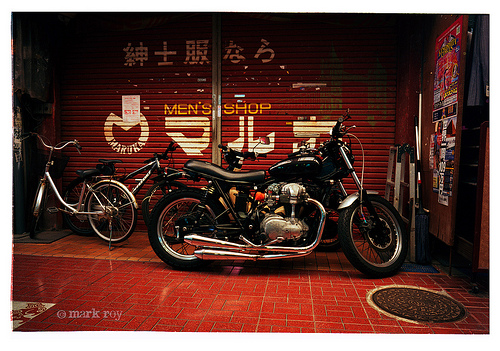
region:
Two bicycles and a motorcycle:
[26, 127, 431, 304]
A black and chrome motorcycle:
[138, 127, 425, 304]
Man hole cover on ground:
[363, 278, 467, 338]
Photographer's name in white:
[53, 303, 130, 325]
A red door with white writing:
[61, 69, 395, 240]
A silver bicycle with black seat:
[25, 134, 135, 250]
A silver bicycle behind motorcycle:
[21, 123, 140, 255]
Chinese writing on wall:
[115, 37, 300, 84]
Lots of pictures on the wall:
[424, 32, 469, 224]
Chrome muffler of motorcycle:
[177, 226, 310, 270]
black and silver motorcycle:
[182, 137, 374, 265]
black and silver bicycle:
[25, 145, 130, 247]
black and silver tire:
[337, 189, 404, 274]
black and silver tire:
[157, 190, 228, 267]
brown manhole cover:
[374, 281, 459, 327]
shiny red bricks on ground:
[64, 276, 202, 323]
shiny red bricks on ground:
[221, 280, 350, 318]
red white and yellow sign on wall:
[54, 36, 187, 138]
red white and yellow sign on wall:
[139, 37, 257, 144]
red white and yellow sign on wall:
[237, 43, 412, 116]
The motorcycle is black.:
[144, 107, 421, 280]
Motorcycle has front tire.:
[333, 180, 410, 282]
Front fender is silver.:
[333, 182, 384, 210]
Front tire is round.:
[336, 188, 414, 278]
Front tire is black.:
[331, 187, 417, 283]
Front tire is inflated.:
[335, 183, 412, 280]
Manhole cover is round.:
[357, 276, 476, 328]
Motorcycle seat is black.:
[181, 151, 273, 191]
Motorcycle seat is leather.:
[180, 149, 268, 191]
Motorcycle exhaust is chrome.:
[174, 225, 309, 265]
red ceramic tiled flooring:
[81, 263, 248, 329]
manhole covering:
[344, 280, 497, 323]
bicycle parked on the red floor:
[29, 128, 129, 243]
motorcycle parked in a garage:
[179, 152, 404, 274]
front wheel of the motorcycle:
[355, 196, 416, 281]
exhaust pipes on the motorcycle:
[177, 220, 321, 266]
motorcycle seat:
[181, 151, 269, 185]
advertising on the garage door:
[101, 84, 288, 158]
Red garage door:
[28, 21, 402, 200]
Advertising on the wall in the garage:
[423, 37, 478, 210]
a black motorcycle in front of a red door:
[151, 112, 408, 276]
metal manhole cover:
[370, 282, 469, 325]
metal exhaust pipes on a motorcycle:
[182, 234, 270, 263]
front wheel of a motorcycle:
[337, 188, 410, 277]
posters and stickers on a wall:
[428, 17, 465, 204]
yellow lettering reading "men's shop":
[163, 97, 275, 116]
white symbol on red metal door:
[104, 103, 154, 154]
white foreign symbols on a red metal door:
[120, 37, 280, 67]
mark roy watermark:
[53, 302, 125, 324]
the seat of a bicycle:
[97, 157, 122, 165]